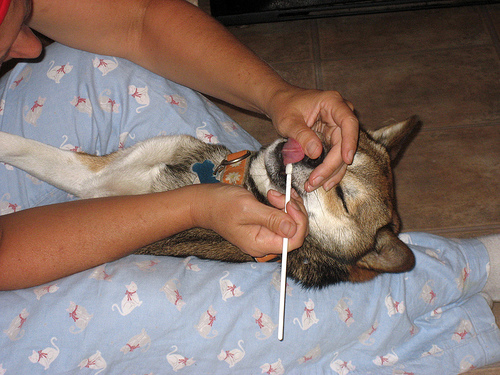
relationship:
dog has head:
[3, 75, 438, 299] [248, 91, 431, 291]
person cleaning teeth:
[0, 0, 500, 358] [262, 132, 329, 203]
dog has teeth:
[3, 75, 438, 299] [262, 132, 329, 203]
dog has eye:
[3, 75, 438, 299] [321, 180, 359, 222]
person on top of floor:
[0, 0, 500, 358] [211, 13, 496, 242]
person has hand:
[0, 0, 500, 358] [30, 6, 377, 199]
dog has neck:
[3, 75, 438, 299] [211, 149, 299, 269]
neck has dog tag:
[211, 149, 299, 269] [195, 142, 229, 197]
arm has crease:
[30, 6, 377, 199] [129, 8, 186, 91]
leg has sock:
[4, 241, 498, 374] [464, 223, 500, 307]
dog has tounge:
[3, 75, 438, 299] [279, 140, 305, 169]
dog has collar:
[3, 75, 438, 299] [220, 147, 253, 203]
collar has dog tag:
[220, 147, 253, 203] [190, 157, 225, 184]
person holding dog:
[4, 2, 499, 369] [3, 75, 438, 299]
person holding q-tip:
[4, 2, 499, 369] [274, 166, 299, 344]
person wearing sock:
[4, 2, 499, 369] [464, 223, 500, 307]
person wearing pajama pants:
[4, 2, 499, 369] [9, 71, 482, 372]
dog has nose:
[3, 75, 438, 299] [307, 141, 326, 173]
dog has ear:
[3, 75, 438, 299] [360, 108, 427, 172]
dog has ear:
[3, 75, 438, 299] [356, 228, 420, 283]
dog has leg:
[3, 75, 438, 299] [4, 115, 219, 218]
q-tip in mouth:
[276, 162, 295, 342] [252, 140, 306, 212]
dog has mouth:
[3, 75, 438, 299] [252, 140, 306, 212]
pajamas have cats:
[9, 71, 482, 372] [50, 75, 168, 139]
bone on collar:
[193, 158, 219, 199] [220, 147, 253, 203]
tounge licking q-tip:
[279, 140, 305, 169] [276, 162, 295, 342]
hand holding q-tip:
[30, 6, 377, 199] [276, 162, 295, 342]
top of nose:
[24, 42, 41, 61] [7, 30, 53, 72]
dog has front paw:
[3, 75, 438, 299] [2, 132, 37, 176]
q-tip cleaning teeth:
[274, 166, 299, 344] [262, 132, 329, 203]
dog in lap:
[3, 75, 438, 299] [10, 52, 214, 310]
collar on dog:
[220, 147, 253, 203] [3, 75, 438, 299]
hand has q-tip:
[30, 6, 377, 199] [274, 166, 299, 344]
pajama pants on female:
[0, 40, 500, 375] [4, 2, 499, 369]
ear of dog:
[360, 108, 427, 172] [3, 75, 438, 299]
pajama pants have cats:
[0, 40, 500, 375] [50, 75, 168, 139]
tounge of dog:
[279, 140, 305, 169] [3, 75, 438, 299]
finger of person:
[286, 109, 326, 171] [4, 2, 499, 369]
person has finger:
[4, 2, 499, 369] [286, 109, 326, 171]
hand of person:
[30, 6, 377, 199] [0, 0, 500, 358]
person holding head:
[0, 0, 500, 358] [251, 92, 433, 321]